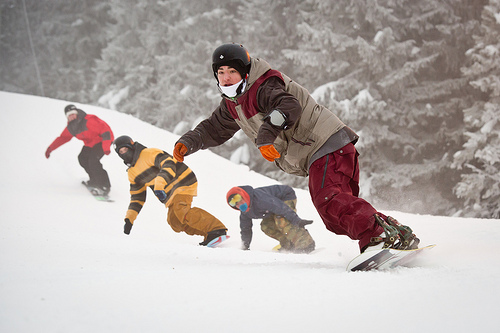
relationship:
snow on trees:
[295, 11, 407, 109] [84, 3, 498, 220]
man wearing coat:
[225, 167, 308, 256] [239, 183, 303, 223]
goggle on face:
[229, 193, 240, 205] [228, 190, 248, 211]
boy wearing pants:
[171, 43, 418, 248] [313, 141, 401, 246]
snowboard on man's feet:
[345, 243, 447, 269] [359, 215, 421, 262]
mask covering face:
[119, 149, 136, 161] [115, 145, 133, 160]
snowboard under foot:
[208, 231, 230, 248] [202, 230, 227, 242]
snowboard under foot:
[208, 231, 230, 248] [195, 234, 212, 247]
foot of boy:
[202, 230, 227, 242] [111, 135, 228, 246]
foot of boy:
[195, 234, 212, 247] [111, 135, 228, 246]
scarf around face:
[216, 78, 252, 100] [216, 63, 245, 94]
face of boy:
[216, 63, 245, 94] [171, 43, 418, 248]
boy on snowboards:
[171, 43, 418, 248] [355, 240, 428, 275]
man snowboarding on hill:
[44, 95, 118, 200] [6, 89, 497, 331]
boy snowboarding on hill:
[111, 135, 228, 246] [6, 89, 497, 331]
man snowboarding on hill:
[225, 183, 316, 253] [6, 89, 497, 331]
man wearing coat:
[44, 95, 118, 200] [47, 110, 114, 154]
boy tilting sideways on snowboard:
[171, 43, 418, 248] [276, 186, 447, 283]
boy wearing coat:
[111, 135, 228, 246] [125, 144, 201, 225]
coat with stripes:
[125, 144, 201, 225] [145, 153, 195, 199]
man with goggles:
[225, 183, 316, 253] [228, 193, 240, 205]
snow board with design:
[39, 182, 135, 291] [215, 236, 223, 246]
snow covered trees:
[56, 252, 216, 320] [3, 0, 499, 214]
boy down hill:
[171, 43, 418, 248] [130, 252, 307, 299]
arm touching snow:
[161, 71, 248, 193] [38, 238, 143, 313]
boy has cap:
[171, 43, 418, 248] [211, 43, 251, 96]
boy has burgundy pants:
[171, 43, 418, 248] [307, 141, 397, 249]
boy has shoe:
[171, 43, 418, 248] [356, 220, 399, 255]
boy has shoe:
[171, 43, 418, 248] [386, 216, 421, 245]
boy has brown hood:
[118, 135, 229, 248] [114, 134, 196, 224]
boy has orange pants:
[111, 135, 228, 246] [167, 195, 227, 236]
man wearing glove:
[44, 95, 118, 200] [45, 148, 48, 155]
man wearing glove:
[44, 95, 118, 200] [104, 149, 111, 154]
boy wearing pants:
[171, 43, 418, 248] [67, 146, 109, 189]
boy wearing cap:
[111, 135, 228, 246] [109, 135, 135, 157]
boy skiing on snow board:
[171, 43, 418, 248] [345, 225, 442, 273]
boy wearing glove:
[171, 43, 418, 248] [257, 142, 281, 164]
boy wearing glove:
[171, 43, 418, 248] [173, 142, 188, 159]